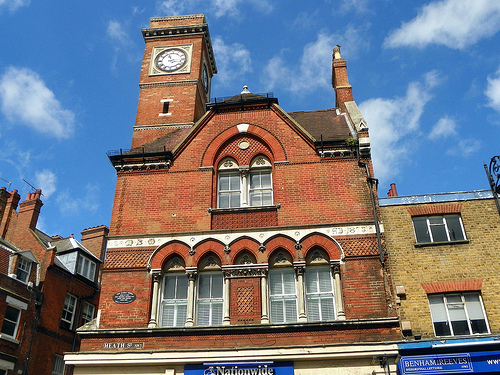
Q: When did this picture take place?
A: It took place in the day time.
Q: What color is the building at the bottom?
A: The building at the bottom is blue and white.